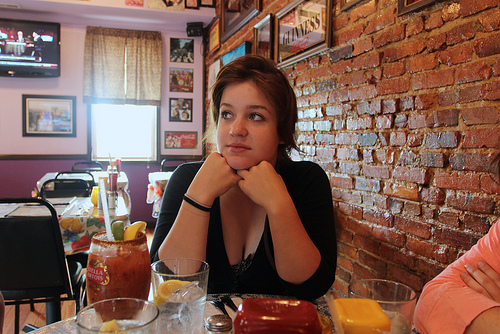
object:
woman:
[148, 54, 338, 301]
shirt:
[412, 214, 499, 334]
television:
[0, 17, 62, 79]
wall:
[0, 0, 218, 226]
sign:
[270, 1, 333, 68]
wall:
[204, 0, 496, 308]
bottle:
[232, 298, 322, 334]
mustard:
[332, 296, 389, 333]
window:
[87, 29, 163, 162]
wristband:
[181, 193, 212, 213]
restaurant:
[0, 1, 499, 334]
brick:
[409, 68, 455, 91]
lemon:
[152, 280, 202, 305]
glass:
[148, 258, 211, 333]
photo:
[21, 93, 78, 138]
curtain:
[84, 26, 164, 107]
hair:
[194, 55, 308, 163]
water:
[154, 294, 206, 334]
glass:
[86, 230, 152, 325]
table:
[22, 292, 420, 333]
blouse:
[150, 159, 340, 301]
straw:
[100, 178, 114, 241]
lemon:
[123, 221, 147, 243]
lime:
[112, 221, 124, 241]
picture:
[170, 37, 195, 63]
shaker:
[205, 314, 233, 333]